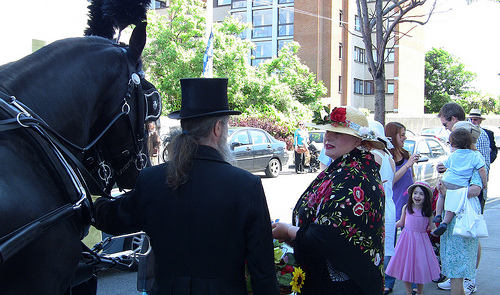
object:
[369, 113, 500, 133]
fence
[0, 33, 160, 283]
black horse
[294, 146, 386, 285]
jacket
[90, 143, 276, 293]
jacket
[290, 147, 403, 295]
shawl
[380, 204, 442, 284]
dress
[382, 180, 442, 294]
young girl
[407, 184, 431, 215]
brown hair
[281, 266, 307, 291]
sunflower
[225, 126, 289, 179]
car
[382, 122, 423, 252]
woman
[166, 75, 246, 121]
hat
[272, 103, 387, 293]
woman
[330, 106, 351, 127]
flower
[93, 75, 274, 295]
man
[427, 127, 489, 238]
child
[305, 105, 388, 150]
cover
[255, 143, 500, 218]
street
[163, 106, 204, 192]
hair